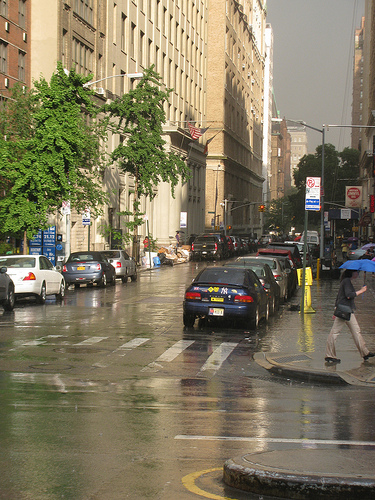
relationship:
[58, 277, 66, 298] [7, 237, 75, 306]
wheel on vehicle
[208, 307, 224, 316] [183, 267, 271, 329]
license plate on car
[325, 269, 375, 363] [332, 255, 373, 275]
person with umbrella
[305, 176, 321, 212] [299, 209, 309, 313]
sign on pole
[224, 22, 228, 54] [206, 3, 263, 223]
window on building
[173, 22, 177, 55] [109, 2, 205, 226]
window on building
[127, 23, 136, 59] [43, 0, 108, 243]
window on building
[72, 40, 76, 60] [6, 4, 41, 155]
window on building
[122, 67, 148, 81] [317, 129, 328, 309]
street light on pole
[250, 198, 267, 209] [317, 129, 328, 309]
street light on pole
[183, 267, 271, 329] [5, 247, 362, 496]
car on street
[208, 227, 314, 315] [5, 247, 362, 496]
car on street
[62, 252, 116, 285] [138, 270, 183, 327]
car on street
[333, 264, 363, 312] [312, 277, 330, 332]
person on sidewalk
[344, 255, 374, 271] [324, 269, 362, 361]
umbrella of person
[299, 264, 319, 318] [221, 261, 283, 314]
sign by car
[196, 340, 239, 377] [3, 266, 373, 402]
line on street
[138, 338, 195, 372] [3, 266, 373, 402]
line on street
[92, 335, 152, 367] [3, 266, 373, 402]
line on street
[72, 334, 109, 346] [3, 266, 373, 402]
line on street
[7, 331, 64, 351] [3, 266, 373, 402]
line on street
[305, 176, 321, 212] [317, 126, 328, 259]
sign on pole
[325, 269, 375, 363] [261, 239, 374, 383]
person on sidewalk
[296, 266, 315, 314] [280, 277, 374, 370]
sign on sidewalk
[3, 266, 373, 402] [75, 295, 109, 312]
street after rain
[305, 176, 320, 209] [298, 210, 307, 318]
sign on pole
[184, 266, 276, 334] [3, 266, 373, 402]
car parked on street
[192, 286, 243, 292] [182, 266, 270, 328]
stickers on back of car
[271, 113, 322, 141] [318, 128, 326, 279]
street light on pole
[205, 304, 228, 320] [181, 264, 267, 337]
license plate on car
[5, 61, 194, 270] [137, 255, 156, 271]
green trees along sidewalk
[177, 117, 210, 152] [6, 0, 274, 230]
american flag hung on building